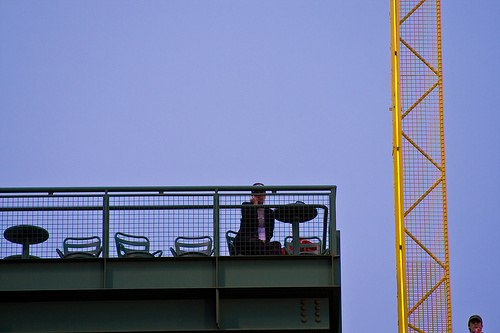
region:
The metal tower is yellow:
[380, 11, 457, 328]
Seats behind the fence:
[38, 209, 321, 266]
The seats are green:
[54, 217, 313, 256]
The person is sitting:
[230, 174, 291, 257]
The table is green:
[268, 194, 318, 261]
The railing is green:
[6, 178, 338, 265]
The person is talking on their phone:
[227, 177, 288, 258]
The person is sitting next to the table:
[234, 174, 283, 246]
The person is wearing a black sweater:
[233, 181, 277, 239]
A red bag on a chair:
[278, 232, 315, 259]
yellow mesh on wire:
[413, 312, 445, 327]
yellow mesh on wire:
[411, 284, 421, 294]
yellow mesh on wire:
[434, 309, 443, 316]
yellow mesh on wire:
[430, 243, 441, 255]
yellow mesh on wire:
[428, 234, 438, 241]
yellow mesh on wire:
[421, 224, 433, 236]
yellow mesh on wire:
[432, 206, 440, 211]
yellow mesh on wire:
[415, 182, 421, 188]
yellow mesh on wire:
[413, 166, 423, 177]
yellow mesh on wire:
[409, 87, 421, 101]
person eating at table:
[239, 173, 311, 258]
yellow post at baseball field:
[383, 47, 461, 281]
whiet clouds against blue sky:
[12, 15, 57, 62]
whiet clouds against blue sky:
[32, 107, 104, 155]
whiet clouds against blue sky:
[98, 57, 180, 121]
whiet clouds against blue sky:
[152, 92, 229, 147]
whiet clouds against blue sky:
[216, 53, 296, 113]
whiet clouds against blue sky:
[278, 95, 336, 146]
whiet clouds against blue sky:
[245, 15, 327, 79]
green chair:
[49, 229, 109, 270]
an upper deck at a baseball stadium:
[8, 177, 370, 332]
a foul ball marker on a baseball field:
[393, 3, 473, 323]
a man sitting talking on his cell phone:
[234, 175, 318, 282]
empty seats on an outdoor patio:
[10, 216, 215, 268]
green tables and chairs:
[8, 178, 218, 285]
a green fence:
[3, 180, 345, 319]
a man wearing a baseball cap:
[458, 303, 495, 332]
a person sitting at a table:
[232, 174, 339, 265]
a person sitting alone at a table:
[232, 163, 323, 273]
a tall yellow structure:
[381, 0, 451, 330]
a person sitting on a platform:
[9, 116, 414, 331]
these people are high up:
[183, 137, 498, 331]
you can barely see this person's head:
[454, 306, 486, 331]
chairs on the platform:
[53, 221, 234, 261]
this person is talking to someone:
[223, 178, 320, 257]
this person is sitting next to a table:
[244, 177, 320, 255]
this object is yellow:
[374, 9, 459, 331]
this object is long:
[387, 3, 454, 253]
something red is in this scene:
[282, 232, 324, 260]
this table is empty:
[0, 216, 64, 268]